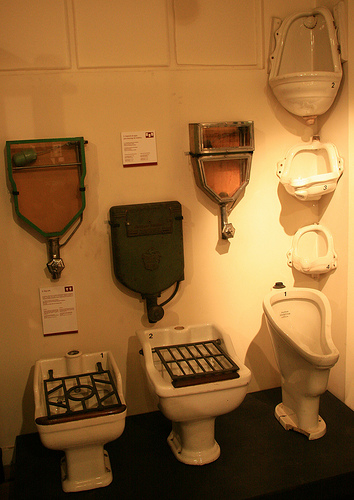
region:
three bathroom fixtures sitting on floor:
[26, 283, 343, 498]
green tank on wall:
[106, 199, 189, 315]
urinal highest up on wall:
[268, 3, 341, 129]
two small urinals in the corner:
[267, 138, 340, 271]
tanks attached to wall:
[5, 100, 255, 322]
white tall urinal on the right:
[260, 290, 331, 445]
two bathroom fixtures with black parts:
[25, 316, 250, 488]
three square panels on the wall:
[5, 2, 265, 68]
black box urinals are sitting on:
[9, 378, 351, 495]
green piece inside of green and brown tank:
[9, 148, 41, 166]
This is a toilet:
[25, 341, 129, 498]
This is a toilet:
[131, 316, 265, 480]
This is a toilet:
[260, 281, 353, 453]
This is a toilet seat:
[21, 351, 139, 427]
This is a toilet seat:
[136, 322, 255, 400]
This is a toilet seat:
[260, 282, 344, 367]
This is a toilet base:
[168, 418, 243, 473]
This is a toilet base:
[59, 448, 131, 495]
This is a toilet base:
[272, 383, 345, 437]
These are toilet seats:
[29, 283, 352, 482]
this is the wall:
[199, 264, 244, 300]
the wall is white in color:
[223, 264, 257, 312]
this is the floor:
[236, 427, 260, 469]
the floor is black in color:
[236, 441, 281, 469]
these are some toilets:
[32, 280, 342, 498]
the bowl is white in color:
[72, 428, 95, 456]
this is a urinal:
[289, 225, 335, 268]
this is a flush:
[44, 254, 77, 282]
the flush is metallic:
[44, 255, 73, 278]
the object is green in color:
[167, 239, 180, 272]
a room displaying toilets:
[5, 2, 350, 495]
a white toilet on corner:
[259, 6, 349, 139]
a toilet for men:
[263, 7, 345, 124]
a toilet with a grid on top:
[26, 341, 134, 495]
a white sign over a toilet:
[28, 277, 130, 491]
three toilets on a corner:
[267, 0, 347, 290]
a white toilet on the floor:
[248, 278, 348, 436]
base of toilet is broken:
[262, 341, 330, 446]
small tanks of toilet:
[185, 107, 260, 245]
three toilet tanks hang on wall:
[3, 106, 262, 324]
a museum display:
[5, 13, 352, 492]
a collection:
[5, 2, 351, 498]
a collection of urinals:
[10, 4, 350, 491]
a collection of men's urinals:
[5, 7, 350, 497]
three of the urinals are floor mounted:
[23, 279, 342, 493]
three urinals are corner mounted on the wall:
[271, 7, 352, 279]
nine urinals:
[7, 11, 352, 479]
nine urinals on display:
[7, 3, 344, 496]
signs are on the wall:
[23, 116, 164, 345]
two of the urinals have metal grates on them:
[28, 316, 249, 489]